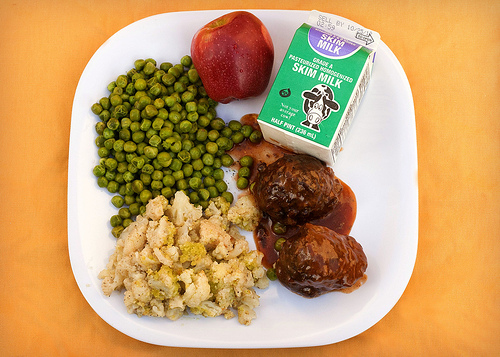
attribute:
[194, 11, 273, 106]
apple — red, whole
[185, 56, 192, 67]
pea — green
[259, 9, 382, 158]
skim milk —  skim,  in carton, green, in box, small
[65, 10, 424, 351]
plate — white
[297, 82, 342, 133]
cow — a drawing, black, white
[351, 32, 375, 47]
arrow — pointing, black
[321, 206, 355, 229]
sauce — red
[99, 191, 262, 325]
chunk — yellow, seasoned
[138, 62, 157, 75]
pea — green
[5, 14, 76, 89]
tabletop — orange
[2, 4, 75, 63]
table — wooden, orange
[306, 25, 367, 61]
carton — purple